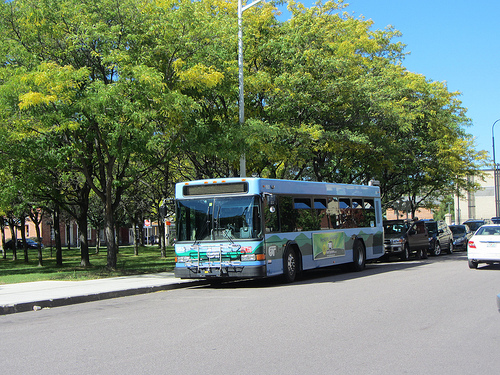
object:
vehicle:
[465, 223, 499, 268]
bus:
[174, 176, 387, 288]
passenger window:
[291, 200, 315, 231]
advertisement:
[310, 229, 346, 260]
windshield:
[178, 197, 263, 242]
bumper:
[174, 236, 265, 280]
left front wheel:
[282, 241, 301, 284]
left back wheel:
[351, 235, 368, 270]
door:
[406, 221, 431, 252]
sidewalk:
[0, 268, 210, 315]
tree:
[0, 0, 213, 271]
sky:
[0, 0, 500, 172]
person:
[408, 215, 428, 262]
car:
[385, 217, 430, 260]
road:
[0, 245, 499, 375]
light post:
[237, 1, 264, 179]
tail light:
[468, 242, 477, 249]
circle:
[242, 177, 247, 180]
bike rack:
[186, 243, 246, 271]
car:
[419, 219, 457, 255]